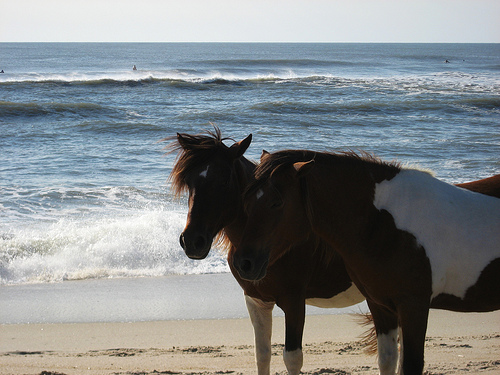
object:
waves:
[13, 60, 197, 115]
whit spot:
[403, 182, 459, 242]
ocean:
[0, 41, 498, 286]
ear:
[229, 132, 256, 155]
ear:
[172, 131, 193, 149]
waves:
[1, 66, 493, 93]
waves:
[0, 195, 208, 258]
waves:
[1, 31, 500, 265]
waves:
[266, 98, 498, 110]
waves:
[204, 57, 339, 65]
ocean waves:
[110, 185, 150, 208]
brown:
[199, 193, 221, 208]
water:
[0, 37, 497, 295]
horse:
[237, 136, 495, 371]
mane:
[158, 120, 262, 178]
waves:
[5, 67, 496, 282]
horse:
[171, 127, 362, 374]